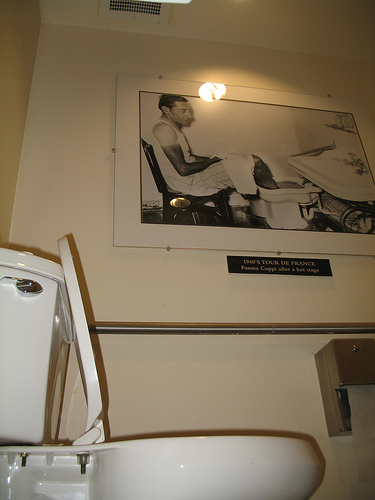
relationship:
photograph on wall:
[104, 65, 374, 258] [4, 23, 373, 428]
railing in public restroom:
[92, 322, 372, 335] [0, 0, 375, 500]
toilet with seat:
[13, 241, 331, 493] [51, 213, 126, 455]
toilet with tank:
[13, 241, 331, 493] [2, 237, 79, 448]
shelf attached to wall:
[311, 338, 374, 437] [0, 0, 374, 498]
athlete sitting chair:
[148, 95, 276, 199] [119, 135, 265, 204]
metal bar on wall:
[89, 315, 374, 335] [0, 0, 374, 498]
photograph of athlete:
[133, 90, 375, 235] [149, 95, 276, 198]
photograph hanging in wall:
[133, 90, 375, 235] [0, 0, 374, 325]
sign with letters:
[223, 254, 335, 277] [282, 255, 321, 266]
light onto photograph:
[190, 80, 235, 107] [133, 90, 375, 235]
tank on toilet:
[0, 247, 70, 451] [13, 241, 331, 493]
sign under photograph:
[227, 254, 331, 277] [133, 90, 375, 235]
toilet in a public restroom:
[0, 234, 328, 500] [7, 16, 362, 493]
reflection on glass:
[195, 80, 229, 105] [170, 153, 274, 210]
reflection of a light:
[195, 80, 238, 107] [200, 77, 223, 107]